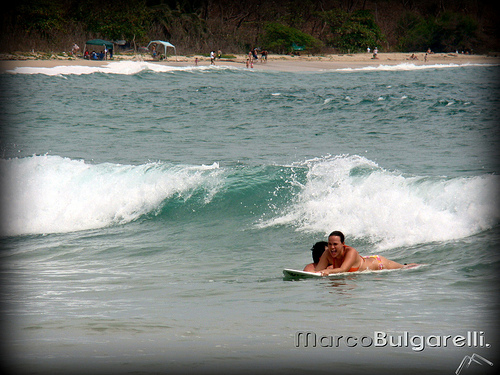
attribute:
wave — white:
[38, 123, 432, 283]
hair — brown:
[332, 227, 359, 247]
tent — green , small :
[114, 19, 215, 91]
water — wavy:
[11, 58, 478, 363]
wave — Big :
[25, 120, 457, 290]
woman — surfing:
[279, 232, 417, 291]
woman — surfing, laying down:
[271, 207, 410, 277]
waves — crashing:
[45, 152, 468, 258]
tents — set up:
[78, 28, 177, 70]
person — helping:
[287, 238, 327, 275]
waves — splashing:
[65, 156, 393, 231]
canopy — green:
[81, 32, 129, 62]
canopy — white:
[130, 28, 200, 78]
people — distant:
[133, 46, 290, 76]